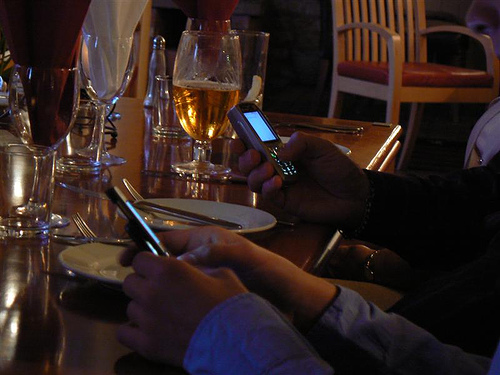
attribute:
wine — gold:
[170, 82, 233, 148]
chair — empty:
[327, 1, 495, 112]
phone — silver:
[227, 87, 318, 205]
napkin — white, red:
[1, 9, 139, 75]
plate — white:
[137, 191, 295, 245]